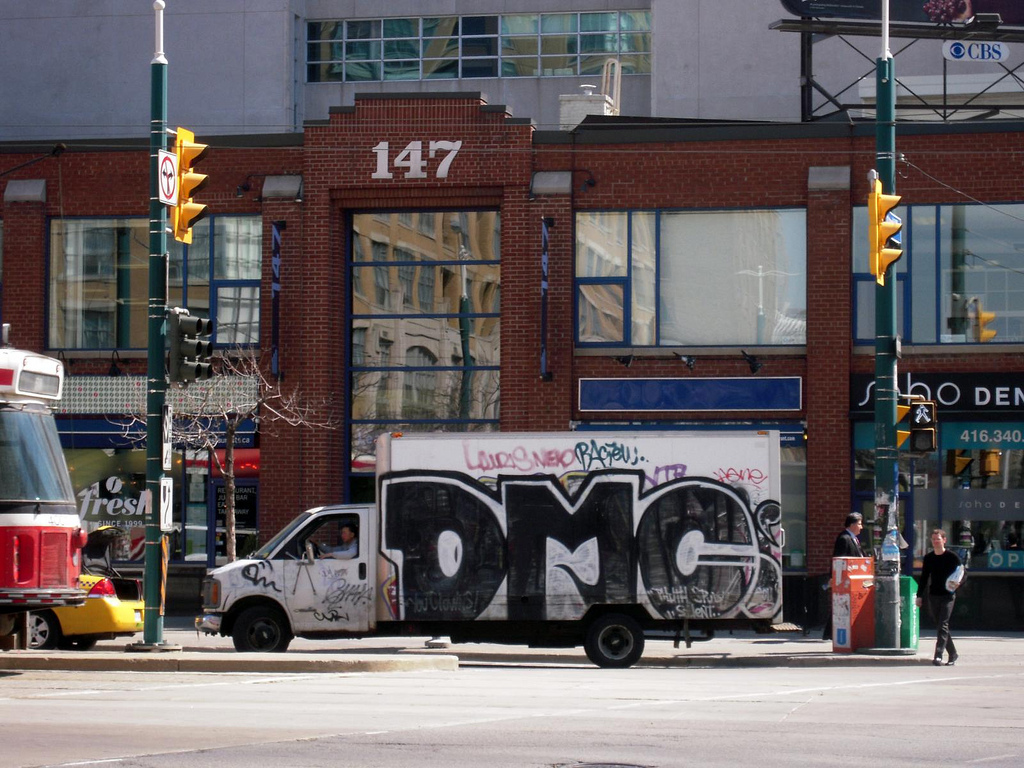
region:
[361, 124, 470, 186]
white numbers on the building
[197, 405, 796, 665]
white and black truck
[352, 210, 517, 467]
reflection in the window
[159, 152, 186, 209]
red, white, and black sign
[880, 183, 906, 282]
a row of three lights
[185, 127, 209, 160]
yellow cone around the light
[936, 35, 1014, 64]
blue CBS logo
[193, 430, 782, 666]
Graffiti covered box truck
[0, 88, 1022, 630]
Red brick building.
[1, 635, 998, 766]
Street crosswalk.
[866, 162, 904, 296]
Yellow painted traffic signal.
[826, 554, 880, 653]
Red colored newspaper box.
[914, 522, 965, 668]
Man wearing a black shirt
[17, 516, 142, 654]
Rear of yellow car with trunk open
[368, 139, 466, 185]
Large white numerals depicting a building address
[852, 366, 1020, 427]
Sign depicting a shop's name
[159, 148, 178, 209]
White, red, and black traffic sign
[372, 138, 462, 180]
A white number marked on the top of an entranceway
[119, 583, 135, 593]
The empty trunk of a car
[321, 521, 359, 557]
A driver behind the wheel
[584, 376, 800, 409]
A blue strip on a brick building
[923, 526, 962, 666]
A man walking beside a green bin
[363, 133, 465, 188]
address of the building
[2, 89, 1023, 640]
red brick and cement building with retail shops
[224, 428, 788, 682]
a panel truck covered in graffitti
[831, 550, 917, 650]
boxes to sell newspapers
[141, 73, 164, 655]
green pole holding traffic lights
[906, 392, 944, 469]
light for the crosswalk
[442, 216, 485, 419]
reflection of the street light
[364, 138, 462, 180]
Number 147 on front of brick building.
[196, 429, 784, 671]
White moving truck covered in graffiti.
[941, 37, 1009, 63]
CBS sign under billboard.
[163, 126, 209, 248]
the traffic light is on a pole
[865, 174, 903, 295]
the traffic light is on a pole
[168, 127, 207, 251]
the traffic light is above the street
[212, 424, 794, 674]
a truck is passing by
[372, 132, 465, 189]
large numbers are on the building front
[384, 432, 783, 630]
graffiti is painted on the truck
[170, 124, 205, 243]
the traffic light is painted yellow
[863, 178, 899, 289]
the traffic light is painted yellow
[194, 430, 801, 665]
the graffiti on the truck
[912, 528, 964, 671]
the man is walking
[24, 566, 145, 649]
the taxi is yellow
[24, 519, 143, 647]
the taxi trunk is opened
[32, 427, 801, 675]
the truck is behind the taxi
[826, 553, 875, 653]
the stand is red and white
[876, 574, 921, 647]
the stand is green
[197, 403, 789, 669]
White box truck with covered in graffiti.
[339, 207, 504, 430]
Large window with blue panes in brick building.